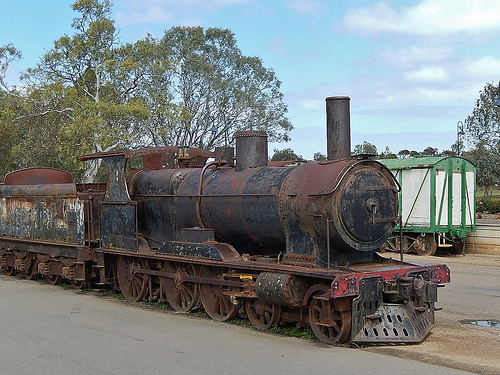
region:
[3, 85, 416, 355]
VERY OLD BLACK TRAIN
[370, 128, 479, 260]
GREEN AND WHITE TRAIN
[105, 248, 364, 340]
WHEELS ON A TRAIN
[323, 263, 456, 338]
FRONT OF A TRAIN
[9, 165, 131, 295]
RUSTED PART OF TRAIN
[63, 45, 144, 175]
PART OF A TALL TREE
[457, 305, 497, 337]
PUDDLE OF WATER ON GROUND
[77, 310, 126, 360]
PART OF A ROAD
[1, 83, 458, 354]
long rusted train on ground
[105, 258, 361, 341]
wheels on side of train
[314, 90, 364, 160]
chute on top of train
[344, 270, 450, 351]
metal grill on front of train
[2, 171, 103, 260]
rusted train car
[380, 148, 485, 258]
green and white train car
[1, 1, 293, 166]
tall green trees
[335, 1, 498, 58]
white cloud in blue sky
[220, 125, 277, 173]
short chute on top of train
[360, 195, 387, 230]
lever knob on front of train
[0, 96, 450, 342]
Old rusted and discarded train in a railway junkyard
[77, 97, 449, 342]
An old steam engine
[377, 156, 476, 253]
Green closed goods carriage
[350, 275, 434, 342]
Cow guard in front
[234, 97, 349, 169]
Steam exhausts of the engine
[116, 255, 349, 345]
Steel wheels now rusted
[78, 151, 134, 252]
Operater's cabin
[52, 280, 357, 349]
Grass growing under the discarded train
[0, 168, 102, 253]
Coal storage wagon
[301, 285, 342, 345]
wheel of a train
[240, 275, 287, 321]
wheel of a tire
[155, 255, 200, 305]
wheel of a train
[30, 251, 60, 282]
wheel of a train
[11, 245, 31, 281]
wheel of a train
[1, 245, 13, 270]
wheel of a train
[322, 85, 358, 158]
the chimney of a train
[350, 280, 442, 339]
the bumper of a train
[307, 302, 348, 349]
the front wheel of a train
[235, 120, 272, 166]
the smoke pipe of a train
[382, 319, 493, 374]
the ground tracks of a train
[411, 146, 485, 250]
a train car that is green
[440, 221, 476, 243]
the end piece of a train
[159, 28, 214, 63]
the leaves in a tree